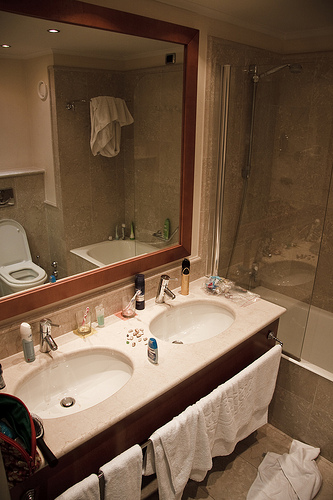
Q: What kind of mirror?
A: Bathroom.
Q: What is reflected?
A: Toilet.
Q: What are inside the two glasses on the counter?
A: Toothbrushes.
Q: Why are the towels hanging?
A: So they can dry.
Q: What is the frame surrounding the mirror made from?
A: Wood.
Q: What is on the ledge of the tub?
A: Soap and shampoo.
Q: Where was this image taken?
A: In a bathroom.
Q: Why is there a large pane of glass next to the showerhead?
A: To prevent water from getting everywhere.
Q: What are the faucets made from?
A: Metal.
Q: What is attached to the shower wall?
A: A towel rack.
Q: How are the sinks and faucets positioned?
A: They are in front of the mirror.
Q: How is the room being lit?
A: The lights in the ceiling.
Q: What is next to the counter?
A: The bathtub.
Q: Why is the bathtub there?
A: So people can take showers or baths.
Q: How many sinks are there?
A: Two.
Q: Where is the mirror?
A: Above the sinks.